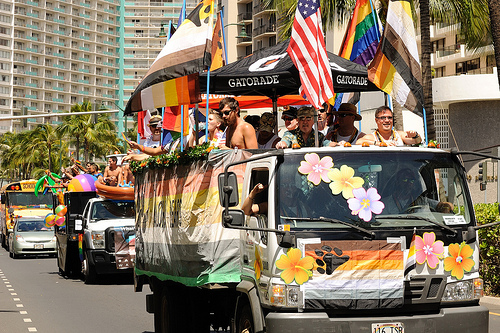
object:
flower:
[273, 246, 316, 286]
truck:
[132, 138, 491, 333]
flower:
[407, 231, 446, 269]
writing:
[225, 76, 282, 89]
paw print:
[311, 241, 352, 278]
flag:
[285, 0, 336, 117]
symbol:
[245, 53, 289, 72]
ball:
[68, 172, 99, 192]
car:
[7, 215, 58, 260]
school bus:
[0, 178, 57, 233]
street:
[1, 180, 500, 332]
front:
[270, 149, 488, 332]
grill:
[269, 275, 487, 329]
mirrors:
[216, 172, 240, 208]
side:
[128, 149, 288, 298]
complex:
[0, 0, 183, 161]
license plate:
[369, 321, 402, 332]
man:
[215, 96, 259, 149]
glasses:
[217, 109, 235, 118]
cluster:
[0, 98, 124, 160]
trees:
[51, 94, 121, 182]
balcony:
[431, 66, 499, 105]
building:
[430, 0, 498, 205]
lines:
[0, 263, 48, 333]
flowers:
[295, 152, 386, 222]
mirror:
[358, 163, 385, 174]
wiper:
[278, 214, 381, 242]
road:
[0, 245, 151, 333]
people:
[271, 97, 396, 150]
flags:
[349, 0, 427, 118]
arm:
[239, 182, 268, 216]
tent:
[193, 36, 382, 98]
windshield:
[281, 153, 465, 230]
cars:
[52, 196, 137, 284]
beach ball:
[66, 172, 97, 194]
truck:
[49, 173, 139, 283]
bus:
[0, 177, 56, 233]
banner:
[300, 240, 404, 310]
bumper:
[266, 306, 487, 331]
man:
[378, 167, 454, 215]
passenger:
[234, 164, 323, 220]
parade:
[0, 19, 465, 301]